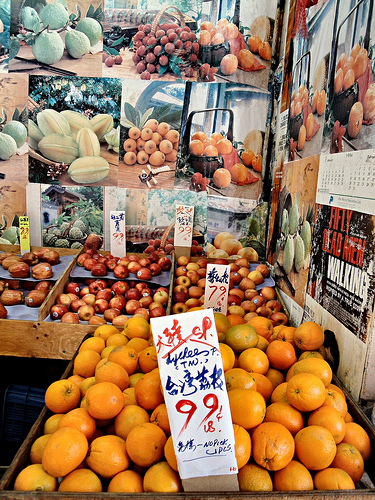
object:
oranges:
[14, 314, 372, 494]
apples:
[49, 247, 171, 323]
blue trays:
[0, 242, 275, 359]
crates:
[0, 236, 373, 496]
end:
[296, 389, 300, 393]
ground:
[321, 97, 342, 124]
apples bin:
[42, 243, 173, 327]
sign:
[320, 207, 370, 300]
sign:
[110, 211, 126, 258]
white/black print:
[314, 149, 374, 215]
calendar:
[317, 0, 375, 216]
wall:
[273, 0, 374, 403]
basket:
[195, 43, 231, 66]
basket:
[331, 0, 373, 130]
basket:
[287, 51, 312, 146]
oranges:
[188, 130, 262, 191]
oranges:
[199, 16, 271, 81]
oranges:
[334, 45, 375, 138]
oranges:
[288, 83, 324, 160]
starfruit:
[29, 108, 120, 183]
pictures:
[0, 1, 104, 77]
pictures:
[305, 201, 374, 345]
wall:
[0, 0, 276, 248]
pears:
[20, 1, 102, 66]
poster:
[115, 80, 179, 190]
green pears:
[17, 0, 102, 65]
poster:
[275, 152, 319, 312]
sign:
[204, 264, 231, 317]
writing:
[205, 266, 229, 313]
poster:
[21, 76, 130, 191]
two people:
[198, 40, 232, 63]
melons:
[0, 131, 17, 160]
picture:
[175, 110, 293, 237]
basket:
[182, 107, 234, 183]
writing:
[154, 315, 238, 473]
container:
[0, 379, 45, 466]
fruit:
[1, 246, 370, 490]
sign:
[148, 306, 239, 481]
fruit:
[119, 114, 183, 166]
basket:
[133, 5, 192, 73]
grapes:
[129, 19, 197, 77]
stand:
[1, 0, 372, 497]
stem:
[295, 388, 299, 393]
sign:
[18, 216, 30, 254]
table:
[68, 147, 121, 186]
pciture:
[28, 76, 123, 186]